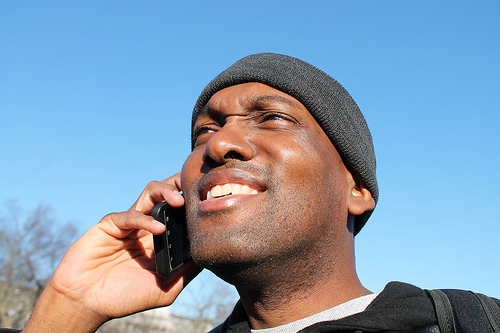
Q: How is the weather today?
A: It is clear.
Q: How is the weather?
A: It is clear.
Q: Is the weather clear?
A: Yes, it is clear.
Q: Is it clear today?
A: Yes, it is clear.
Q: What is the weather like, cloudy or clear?
A: It is clear.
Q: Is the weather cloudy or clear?
A: It is clear.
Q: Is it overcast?
A: No, it is clear.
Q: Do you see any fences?
A: No, there are no fences.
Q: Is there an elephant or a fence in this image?
A: No, there are no fences or elephants.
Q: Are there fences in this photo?
A: No, there are no fences.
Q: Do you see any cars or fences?
A: No, there are no fences or cars.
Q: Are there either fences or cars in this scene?
A: No, there are no fences or cars.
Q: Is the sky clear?
A: Yes, the sky is clear.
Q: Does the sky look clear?
A: Yes, the sky is clear.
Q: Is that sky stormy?
A: No, the sky is clear.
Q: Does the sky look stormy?
A: No, the sky is clear.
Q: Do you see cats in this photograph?
A: No, there are no cats.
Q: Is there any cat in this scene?
A: No, there are no cats.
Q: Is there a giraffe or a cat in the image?
A: No, there are no cats or giraffes.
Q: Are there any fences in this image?
A: No, there are no fences.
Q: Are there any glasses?
A: No, there are no glasses.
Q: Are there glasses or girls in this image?
A: No, there are no glasses or girls.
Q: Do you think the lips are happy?
A: Yes, the lips are happy.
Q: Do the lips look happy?
A: Yes, the lips are happy.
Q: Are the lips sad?
A: No, the lips are happy.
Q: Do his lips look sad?
A: No, the lips are happy.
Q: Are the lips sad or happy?
A: The lips are happy.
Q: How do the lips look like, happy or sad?
A: The lips are happy.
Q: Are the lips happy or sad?
A: The lips are happy.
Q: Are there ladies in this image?
A: No, there are no ladies.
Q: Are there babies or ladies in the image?
A: No, there are no ladies or babies.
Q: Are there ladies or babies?
A: No, there are no ladies or babies.